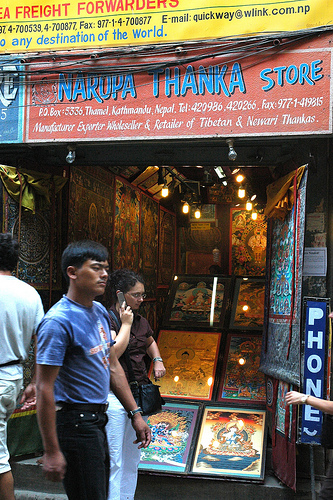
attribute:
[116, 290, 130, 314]
phone — gray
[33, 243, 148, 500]
man — walking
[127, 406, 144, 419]
watch — blue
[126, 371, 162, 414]
bag — black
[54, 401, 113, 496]
pants — black, white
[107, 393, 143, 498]
pants — white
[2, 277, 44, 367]
shirt — white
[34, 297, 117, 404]
shirt — blue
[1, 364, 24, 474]
shorts — khaki, white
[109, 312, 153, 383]
shirt — maroon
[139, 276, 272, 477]
art — framed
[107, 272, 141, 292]
hair — black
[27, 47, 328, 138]
sign — orange, red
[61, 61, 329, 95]
lettering — blue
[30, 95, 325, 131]
letters — white, small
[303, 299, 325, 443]
sign — blue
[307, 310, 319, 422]
phone — white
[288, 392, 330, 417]
forearm — reaching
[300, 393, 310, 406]
watch — silver, gold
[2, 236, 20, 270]
hair — black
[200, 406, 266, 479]
painting — colorful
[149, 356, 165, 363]
watch — blue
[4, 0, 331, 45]
sign — yellow